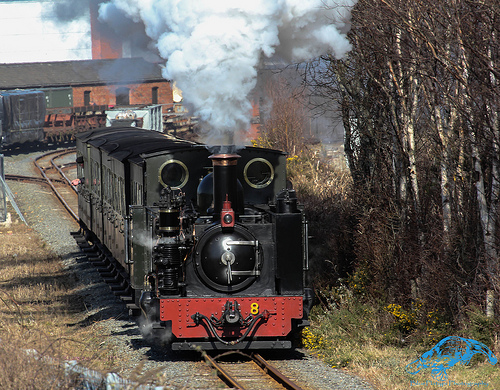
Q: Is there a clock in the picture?
A: No, there are no clocks.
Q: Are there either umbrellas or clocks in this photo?
A: No, there are no clocks or umbrellas.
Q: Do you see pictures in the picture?
A: No, there are no pictures.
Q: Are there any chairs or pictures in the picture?
A: No, there are no pictures or chairs.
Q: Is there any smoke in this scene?
A: Yes, there is smoke.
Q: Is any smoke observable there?
A: Yes, there is smoke.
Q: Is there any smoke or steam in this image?
A: Yes, there is smoke.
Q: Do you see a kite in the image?
A: No, there are no kites.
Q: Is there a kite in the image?
A: No, there are no kites.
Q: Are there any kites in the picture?
A: No, there are no kites.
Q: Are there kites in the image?
A: No, there are no kites.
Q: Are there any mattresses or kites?
A: No, there are no kites or mattresses.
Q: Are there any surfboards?
A: No, there are no surfboards.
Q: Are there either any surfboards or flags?
A: No, there are no surfboards or flags.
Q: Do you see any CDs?
A: No, there are no cds.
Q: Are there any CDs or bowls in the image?
A: No, there are no CDs or bowls.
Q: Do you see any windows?
A: Yes, there are windows.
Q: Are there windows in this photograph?
A: Yes, there are windows.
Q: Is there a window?
A: Yes, there are windows.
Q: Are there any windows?
A: Yes, there are windows.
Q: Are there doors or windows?
A: Yes, there are windows.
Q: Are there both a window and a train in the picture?
A: Yes, there are both a window and a train.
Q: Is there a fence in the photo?
A: No, there are no fences.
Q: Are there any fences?
A: No, there are no fences.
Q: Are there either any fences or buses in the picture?
A: No, there are no fences or buses.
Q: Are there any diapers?
A: No, there are no diapers.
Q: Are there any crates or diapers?
A: No, there are no diapers or crates.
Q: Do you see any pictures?
A: No, there are no pictures.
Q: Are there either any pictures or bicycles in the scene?
A: No, there are no pictures or bicycles.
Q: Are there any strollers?
A: No, there are no strollers.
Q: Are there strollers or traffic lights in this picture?
A: No, there are no strollers or traffic lights.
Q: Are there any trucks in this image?
A: No, there are no trucks.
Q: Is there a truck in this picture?
A: No, there are no trucks.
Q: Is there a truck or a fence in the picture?
A: No, there are no trucks or fences.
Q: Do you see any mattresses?
A: No, there are no mattresses.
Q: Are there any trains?
A: Yes, there is a train.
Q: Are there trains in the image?
A: Yes, there is a train.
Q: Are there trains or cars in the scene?
A: Yes, there is a train.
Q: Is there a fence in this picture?
A: No, there are no fences.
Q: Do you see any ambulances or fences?
A: No, there are no fences or ambulances.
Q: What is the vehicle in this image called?
A: The vehicle is a train.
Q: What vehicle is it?
A: The vehicle is a train.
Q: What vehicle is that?
A: This is a train.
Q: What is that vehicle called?
A: This is a train.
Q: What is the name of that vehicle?
A: This is a train.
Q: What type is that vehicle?
A: This is a train.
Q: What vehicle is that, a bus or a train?
A: This is a train.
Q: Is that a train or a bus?
A: That is a train.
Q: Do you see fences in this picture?
A: No, there are no fences.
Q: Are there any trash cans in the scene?
A: No, there are no trash cans.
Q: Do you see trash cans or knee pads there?
A: No, there are no trash cans or knee pads.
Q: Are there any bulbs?
A: No, there are no bulbs.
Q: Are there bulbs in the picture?
A: No, there are no bulbs.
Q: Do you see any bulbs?
A: No, there are no bulbs.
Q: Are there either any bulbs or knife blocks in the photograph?
A: No, there are no bulbs or knife blocks.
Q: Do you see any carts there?
A: No, there are no carts.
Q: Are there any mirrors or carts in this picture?
A: No, there are no carts or mirrors.